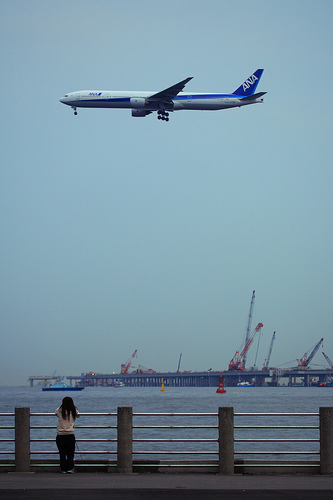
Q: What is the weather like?
A: Overcast.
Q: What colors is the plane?
A: Blue and white.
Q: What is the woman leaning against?
A: A railing.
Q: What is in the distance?
A: A pier.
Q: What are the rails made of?
A: Metal.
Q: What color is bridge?
A: Blue.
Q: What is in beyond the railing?
A: Water.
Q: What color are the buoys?
A: Orange.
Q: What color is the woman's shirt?
A: White.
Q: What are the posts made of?
A: Wood.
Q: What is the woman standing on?
A: Sidewalk.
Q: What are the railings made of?
A: Metal.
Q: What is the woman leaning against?
A: The guardrail.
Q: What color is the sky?
A: Grey.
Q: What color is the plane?
A: White and blue.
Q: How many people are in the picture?
A: One.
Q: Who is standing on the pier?
A: The girl.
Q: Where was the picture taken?
A: The docks.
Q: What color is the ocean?
A: Dark blue.